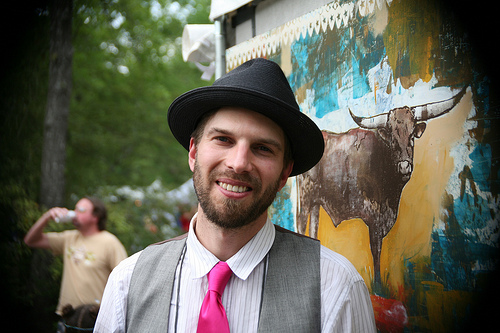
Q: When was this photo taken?
A: In the daytime.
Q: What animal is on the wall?
A: A bull.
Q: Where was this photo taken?
A: At a park.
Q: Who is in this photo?
A: Two men.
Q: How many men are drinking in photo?
A: One.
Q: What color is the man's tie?
A: Pink.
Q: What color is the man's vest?
A: Grey.